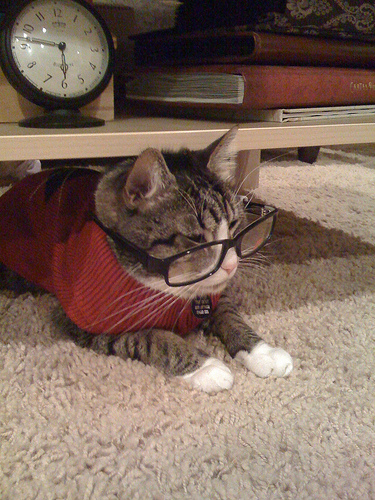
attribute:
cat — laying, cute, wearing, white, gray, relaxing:
[2, 118, 295, 391]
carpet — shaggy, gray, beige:
[1, 140, 361, 492]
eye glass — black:
[101, 195, 281, 291]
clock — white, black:
[1, 2, 120, 128]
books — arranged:
[129, 8, 374, 126]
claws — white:
[184, 341, 300, 392]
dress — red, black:
[2, 166, 217, 337]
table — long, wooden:
[2, 119, 374, 168]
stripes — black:
[174, 157, 231, 223]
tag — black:
[183, 293, 221, 319]